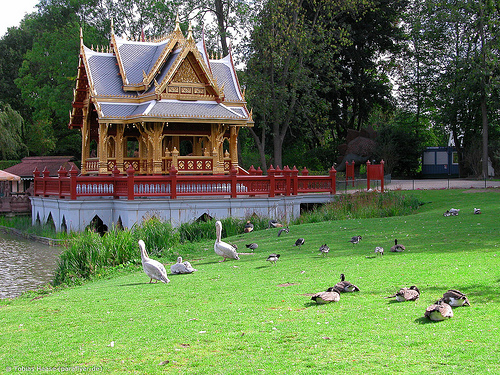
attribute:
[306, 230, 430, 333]
duck — standing, sitting, white, sititng, large, resting, laying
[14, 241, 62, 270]
water — gray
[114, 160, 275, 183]
fence — red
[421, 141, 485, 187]
building — small, pointed, blue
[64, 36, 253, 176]
house — gold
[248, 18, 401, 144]
trees — tall, green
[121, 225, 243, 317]
pelican — white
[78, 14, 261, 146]
gazebo — asian, ornanted, red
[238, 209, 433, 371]
birds — relaxing, long, grey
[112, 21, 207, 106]
roof — grey